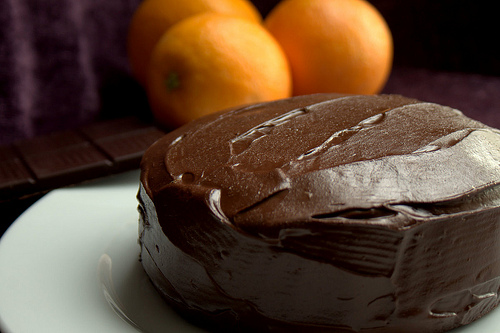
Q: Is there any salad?
A: No, there is no salad.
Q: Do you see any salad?
A: No, there is no salad.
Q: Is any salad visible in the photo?
A: No, there is no salad.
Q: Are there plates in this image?
A: Yes, there is a plate.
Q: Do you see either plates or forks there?
A: Yes, there is a plate.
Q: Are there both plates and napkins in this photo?
A: No, there is a plate but no napkins.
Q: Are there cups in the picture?
A: No, there are no cups.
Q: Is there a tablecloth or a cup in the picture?
A: No, there are no cups or tablecloths.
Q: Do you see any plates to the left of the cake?
A: Yes, there is a plate to the left of the cake.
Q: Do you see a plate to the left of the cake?
A: Yes, there is a plate to the left of the cake.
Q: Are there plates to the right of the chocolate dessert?
A: No, the plate is to the left of the cake.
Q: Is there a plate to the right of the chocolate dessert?
A: No, the plate is to the left of the cake.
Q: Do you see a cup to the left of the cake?
A: No, there is a plate to the left of the cake.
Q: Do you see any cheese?
A: No, there is no cheese.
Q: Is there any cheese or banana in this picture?
A: No, there are no cheese or bananas.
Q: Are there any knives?
A: No, there are no knives.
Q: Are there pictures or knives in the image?
A: No, there are no knives or pictures.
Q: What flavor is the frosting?
A: That is a chocolate frosting.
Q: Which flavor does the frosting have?
A: That is a chocolate frosting.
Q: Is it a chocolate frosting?
A: Yes, that is a chocolate frosting.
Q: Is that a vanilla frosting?
A: No, that is a chocolate frosting.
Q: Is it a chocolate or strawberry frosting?
A: That is a chocolate frosting.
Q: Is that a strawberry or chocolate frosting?
A: That is a chocolate frosting.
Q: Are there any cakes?
A: Yes, there is a cake.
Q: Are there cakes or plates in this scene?
A: Yes, there is a cake.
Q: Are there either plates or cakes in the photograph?
A: Yes, there is a cake.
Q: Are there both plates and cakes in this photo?
A: Yes, there are both a cake and a plate.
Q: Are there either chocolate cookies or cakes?
A: Yes, there is a chocolate cake.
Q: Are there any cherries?
A: No, there are no cherries.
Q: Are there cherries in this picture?
A: No, there are no cherries.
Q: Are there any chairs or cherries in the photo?
A: No, there are no cherries or chairs.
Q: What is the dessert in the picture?
A: The dessert is a cake.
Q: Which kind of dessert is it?
A: The dessert is a cake.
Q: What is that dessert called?
A: This is a cake.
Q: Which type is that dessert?
A: This is a cake.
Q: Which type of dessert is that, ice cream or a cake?
A: This is a cake.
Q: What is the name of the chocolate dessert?
A: The dessert is a cake.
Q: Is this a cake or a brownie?
A: This is a cake.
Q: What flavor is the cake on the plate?
A: This is a chocolate cake.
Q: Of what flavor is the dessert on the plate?
A: This is a chocolate cake.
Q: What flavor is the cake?
A: This is a chocolate cake.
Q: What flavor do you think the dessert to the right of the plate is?
A: This is a chocolate cake.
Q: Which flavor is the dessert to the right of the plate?
A: This is a chocolate cake.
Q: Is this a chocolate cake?
A: Yes, this is a chocolate cake.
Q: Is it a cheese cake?
A: No, this is a chocolate cake.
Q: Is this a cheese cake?
A: No, this is a chocolate cake.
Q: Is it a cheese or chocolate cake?
A: This is a chocolate cake.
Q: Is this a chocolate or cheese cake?
A: This is a chocolate cake.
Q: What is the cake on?
A: The cake is on the plate.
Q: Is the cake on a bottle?
A: No, the cake is on the plate.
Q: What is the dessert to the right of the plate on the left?
A: The dessert is a cake.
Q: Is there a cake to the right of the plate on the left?
A: Yes, there is a cake to the right of the plate.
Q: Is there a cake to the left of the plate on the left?
A: No, the cake is to the right of the plate.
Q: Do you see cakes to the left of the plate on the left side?
A: No, the cake is to the right of the plate.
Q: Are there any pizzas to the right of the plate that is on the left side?
A: No, there is a cake to the right of the plate.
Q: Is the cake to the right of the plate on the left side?
A: Yes, the cake is to the right of the plate.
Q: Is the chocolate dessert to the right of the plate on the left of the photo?
A: Yes, the cake is to the right of the plate.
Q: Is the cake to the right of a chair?
A: No, the cake is to the right of the plate.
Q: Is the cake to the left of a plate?
A: No, the cake is to the right of a plate.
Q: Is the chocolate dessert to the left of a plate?
A: No, the cake is to the right of a plate.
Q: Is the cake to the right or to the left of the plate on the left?
A: The cake is to the right of the plate.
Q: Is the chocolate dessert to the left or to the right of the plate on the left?
A: The cake is to the right of the plate.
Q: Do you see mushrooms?
A: No, there are no mushrooms.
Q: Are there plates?
A: Yes, there is a plate.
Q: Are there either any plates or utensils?
A: Yes, there is a plate.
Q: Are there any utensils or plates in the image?
A: Yes, there is a plate.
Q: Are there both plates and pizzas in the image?
A: No, there is a plate but no pizzas.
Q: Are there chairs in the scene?
A: No, there are no chairs.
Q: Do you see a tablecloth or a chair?
A: No, there are no chairs or tablecloths.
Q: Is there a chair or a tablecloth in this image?
A: No, there are no chairs or tablecloths.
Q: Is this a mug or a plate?
A: This is a plate.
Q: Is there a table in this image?
A: Yes, there is a table.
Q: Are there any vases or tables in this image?
A: Yes, there is a table.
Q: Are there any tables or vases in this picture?
A: Yes, there is a table.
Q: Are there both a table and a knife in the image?
A: No, there is a table but no knives.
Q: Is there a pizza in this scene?
A: No, there are no pizzas.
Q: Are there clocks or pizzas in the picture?
A: No, there are no pizzas or clocks.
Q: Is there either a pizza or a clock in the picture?
A: No, there are no pizzas or clocks.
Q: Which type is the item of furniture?
A: The piece of furniture is a table.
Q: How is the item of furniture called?
A: The piece of furniture is a table.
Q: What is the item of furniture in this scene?
A: The piece of furniture is a table.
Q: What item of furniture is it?
A: The piece of furniture is a table.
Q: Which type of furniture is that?
A: This is a table.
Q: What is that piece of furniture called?
A: This is a table.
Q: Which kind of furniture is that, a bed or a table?
A: This is a table.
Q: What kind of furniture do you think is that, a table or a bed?
A: This is a table.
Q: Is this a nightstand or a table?
A: This is a table.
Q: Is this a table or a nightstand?
A: This is a table.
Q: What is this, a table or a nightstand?
A: This is a table.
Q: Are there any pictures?
A: No, there are no pictures.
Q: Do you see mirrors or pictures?
A: No, there are no pictures or mirrors.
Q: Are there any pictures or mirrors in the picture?
A: No, there are no pictures or mirrors.